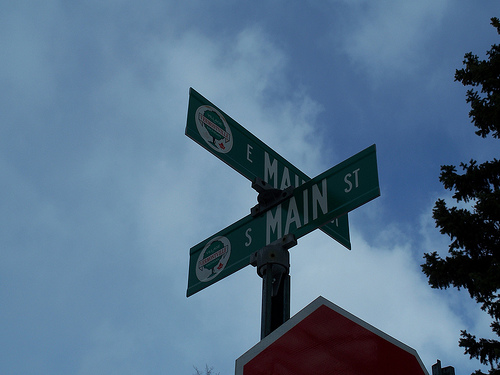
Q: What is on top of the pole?
A: A red sign.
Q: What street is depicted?
A: Main street.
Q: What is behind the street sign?
A: Clouds.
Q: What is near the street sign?
A: A tree.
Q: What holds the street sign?
A: A pole.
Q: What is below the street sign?
A: A sign.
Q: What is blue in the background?
A: The sky.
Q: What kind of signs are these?
A: Street signs.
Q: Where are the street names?
A: On green signs.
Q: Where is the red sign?
A: Below street sings.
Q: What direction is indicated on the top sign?
A: East.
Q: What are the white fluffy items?
A: Clouds.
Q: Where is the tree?
A: On the right.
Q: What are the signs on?
A: Pole.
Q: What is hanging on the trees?
A: Leaves.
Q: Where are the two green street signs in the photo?
A: Behind the building.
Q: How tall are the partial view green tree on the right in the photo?
A: Very tall.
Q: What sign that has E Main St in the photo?
A: The sign with white letters.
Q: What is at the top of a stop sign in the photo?
A: A white and red building.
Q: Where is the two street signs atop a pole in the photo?
A: In front of the white and blue clouds.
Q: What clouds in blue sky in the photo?
A: Clouds behind the signs.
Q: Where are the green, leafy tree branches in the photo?
A: Green leafy tree branches high in the sky.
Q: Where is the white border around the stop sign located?
A: On the pole.